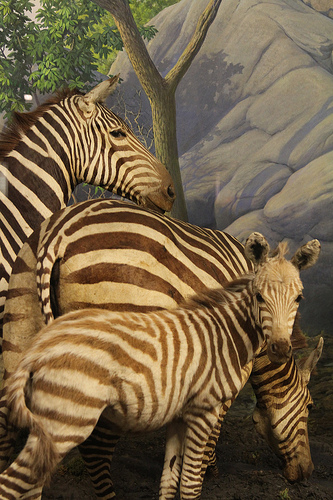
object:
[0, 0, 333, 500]
zoo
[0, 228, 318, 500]
zebra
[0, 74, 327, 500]
group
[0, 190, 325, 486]
zebra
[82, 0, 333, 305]
mountain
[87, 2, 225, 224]
tree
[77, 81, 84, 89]
leaf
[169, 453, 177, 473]
spot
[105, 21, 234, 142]
shadow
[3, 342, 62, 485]
tail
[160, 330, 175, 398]
pattern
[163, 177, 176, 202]
nose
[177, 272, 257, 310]
mane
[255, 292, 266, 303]
eye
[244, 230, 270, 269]
ear